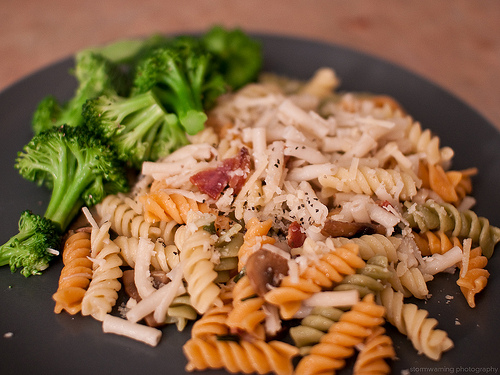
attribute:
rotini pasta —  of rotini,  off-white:
[167, 211, 231, 313]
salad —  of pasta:
[117, 57, 407, 282]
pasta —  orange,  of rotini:
[49, 65, 498, 373]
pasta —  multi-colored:
[184, 125, 416, 310]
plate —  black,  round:
[1, 11, 497, 371]